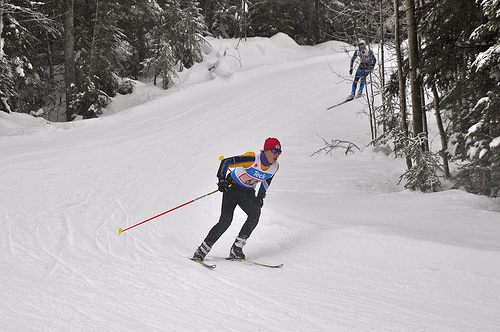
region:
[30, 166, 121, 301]
Ski marks on the snow.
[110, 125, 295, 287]
Cross country skier in the lead.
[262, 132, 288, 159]
Man wearing blue goggles.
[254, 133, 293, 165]
Skier wearing a red hat.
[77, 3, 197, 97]
Snow covered trees on the trail.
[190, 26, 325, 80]
Snow banks beside the trail.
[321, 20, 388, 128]
Another skier trying to catch up.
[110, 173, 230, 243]
Orange and white ski pole.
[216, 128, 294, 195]
Skier wearing a number for the race.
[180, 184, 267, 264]
Man wearing black ski pants.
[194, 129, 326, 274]
a man on skis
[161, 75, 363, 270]
a man on skis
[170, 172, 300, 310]
a man on skis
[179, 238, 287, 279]
Man on skis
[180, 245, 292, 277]
Man is on skis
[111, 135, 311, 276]
Man on the snow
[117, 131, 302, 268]
Man is on the snow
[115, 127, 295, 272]
Man skiing on the snow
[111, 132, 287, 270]
Man is skiing on the snow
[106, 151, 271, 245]
Man holding ski poles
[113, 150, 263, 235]
Man is holding ski poles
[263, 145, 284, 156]
Man wearing sunglasses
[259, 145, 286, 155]
Man is wearing sunglasses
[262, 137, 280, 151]
a red cap on a person's head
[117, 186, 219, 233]
a ski pole in a person's hand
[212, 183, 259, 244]
black pants on a person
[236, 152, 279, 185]
a racing vest on a person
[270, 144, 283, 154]
sunglasses on a person's face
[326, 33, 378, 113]
a person visible through the trees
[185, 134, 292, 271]
a person skiing down a slope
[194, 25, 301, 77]
a pile of snow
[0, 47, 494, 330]
a white snowy slope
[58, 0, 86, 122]
a tree next to a ski trail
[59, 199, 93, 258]
a track in snow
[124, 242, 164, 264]
a track in snow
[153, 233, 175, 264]
a track in snow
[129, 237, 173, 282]
a track in snow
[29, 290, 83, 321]
a track in snow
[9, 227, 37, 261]
a track in snow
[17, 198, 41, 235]
a track in snow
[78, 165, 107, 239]
a track in snow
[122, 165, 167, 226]
a track in snow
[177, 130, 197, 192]
a track in snow